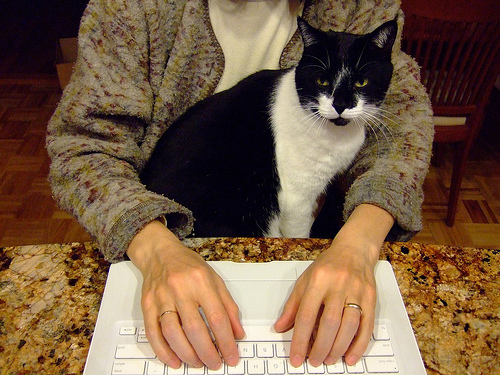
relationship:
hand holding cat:
[267, 240, 384, 358] [193, 17, 409, 202]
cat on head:
[137, 14, 399, 234] [293, 12, 398, 127]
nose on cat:
[329, 101, 351, 116] [137, 14, 399, 234]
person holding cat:
[43, 1, 435, 367] [137, 16, 399, 238]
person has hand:
[43, 1, 435, 367] [129, 225, 246, 369]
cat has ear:
[137, 14, 399, 234] [373, 17, 400, 47]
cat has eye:
[137, 14, 399, 234] [351, 75, 372, 89]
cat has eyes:
[137, 14, 399, 234] [316, 76, 330, 86]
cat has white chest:
[137, 14, 399, 234] [127, 15, 435, 224]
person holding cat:
[43, 1, 435, 367] [137, 14, 399, 234]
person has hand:
[43, 1, 435, 367] [141, 242, 251, 371]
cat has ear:
[137, 14, 399, 234] [293, 15, 323, 44]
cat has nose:
[137, 16, 399, 238] [330, 100, 348, 117]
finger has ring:
[320, 285, 363, 374] [342, 298, 367, 313]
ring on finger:
[158, 310, 175, 318] [156, 297, 199, 368]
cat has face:
[137, 16, 399, 238] [295, 14, 406, 135]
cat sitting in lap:
[137, 14, 399, 234] [124, 201, 408, 250]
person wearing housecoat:
[43, 0, 435, 371] [43, 0, 435, 264]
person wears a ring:
[43, 0, 435, 371] [343, 302, 363, 311]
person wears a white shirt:
[43, 0, 435, 371] [208, 5, 298, 97]